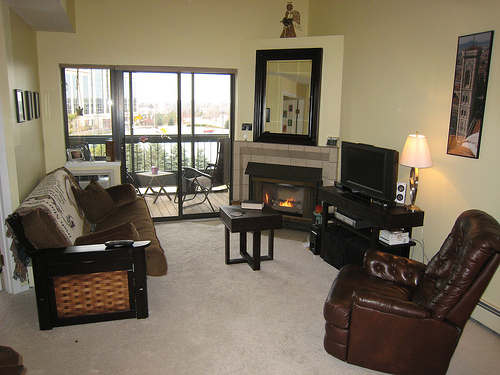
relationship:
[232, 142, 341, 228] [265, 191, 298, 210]
fireplace has fire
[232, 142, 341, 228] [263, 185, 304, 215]
fireplace has place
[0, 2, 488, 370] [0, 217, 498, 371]
room has carpet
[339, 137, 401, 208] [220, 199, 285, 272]
tv behind table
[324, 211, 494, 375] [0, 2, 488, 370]
chair in room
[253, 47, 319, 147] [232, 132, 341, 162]
mirror over mantle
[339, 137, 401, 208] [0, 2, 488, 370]
tv in room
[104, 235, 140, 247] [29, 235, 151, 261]
remote on armrest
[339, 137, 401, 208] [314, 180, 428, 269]
tv on stand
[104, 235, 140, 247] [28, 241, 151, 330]
remote on end table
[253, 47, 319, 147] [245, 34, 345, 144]
mirror on wall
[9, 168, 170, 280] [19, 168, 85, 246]
sofa with blanket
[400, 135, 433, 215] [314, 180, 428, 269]
lamp on stand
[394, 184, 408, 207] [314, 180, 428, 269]
speakers on stand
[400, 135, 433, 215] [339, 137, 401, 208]
lamp by tv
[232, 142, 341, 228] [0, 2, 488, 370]
fireplace in room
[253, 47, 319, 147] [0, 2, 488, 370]
mirror in room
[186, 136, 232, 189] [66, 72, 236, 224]
chair on balcony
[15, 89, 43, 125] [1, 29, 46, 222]
frames on wall